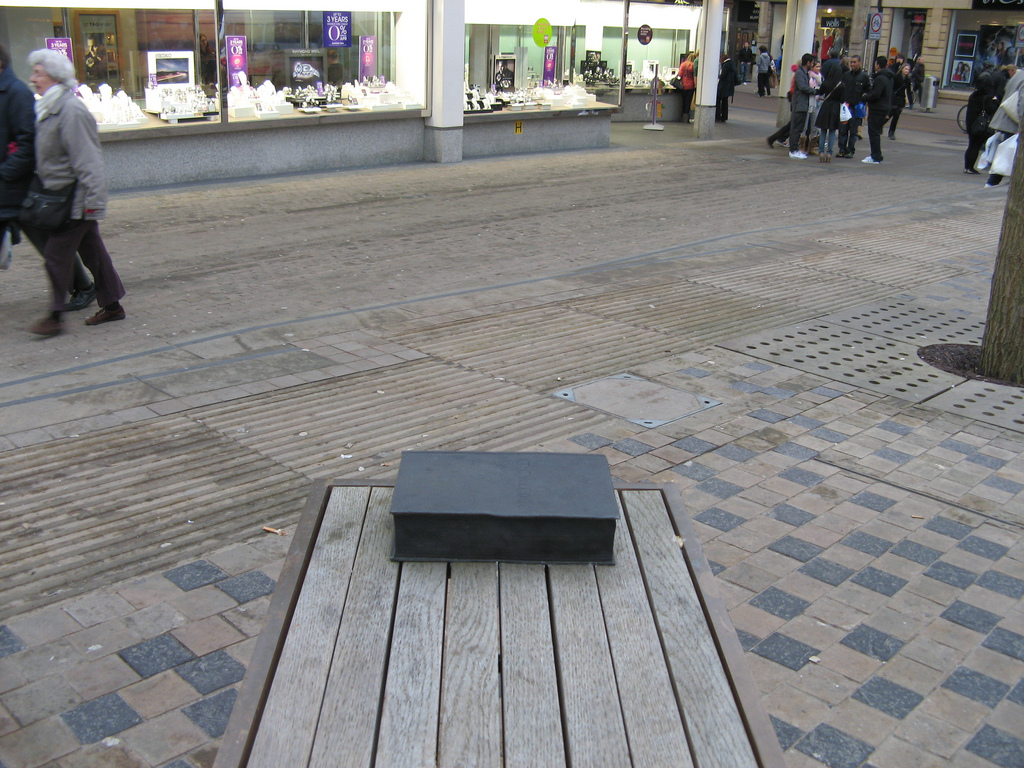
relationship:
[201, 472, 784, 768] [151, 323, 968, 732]
table in ground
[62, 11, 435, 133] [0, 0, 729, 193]
window in a store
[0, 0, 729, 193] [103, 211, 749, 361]
store near a pathway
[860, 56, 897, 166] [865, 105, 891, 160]
person in jeans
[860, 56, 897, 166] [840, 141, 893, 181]
person in shoe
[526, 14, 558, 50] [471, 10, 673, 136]
sign on a window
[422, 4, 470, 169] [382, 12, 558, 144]
pillar on a wall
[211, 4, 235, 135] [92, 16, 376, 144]
divider in a window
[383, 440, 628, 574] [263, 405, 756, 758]
box on a table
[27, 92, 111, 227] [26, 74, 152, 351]
gray coat on a body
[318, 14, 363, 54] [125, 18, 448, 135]
poster on a window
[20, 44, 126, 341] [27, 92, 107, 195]
woman in gray coat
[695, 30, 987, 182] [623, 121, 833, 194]
people walking on sidewalk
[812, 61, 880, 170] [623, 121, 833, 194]
person walking on sidewalk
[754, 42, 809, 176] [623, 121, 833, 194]
person walking on sidewalk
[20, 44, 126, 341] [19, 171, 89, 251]
woman walking with black purse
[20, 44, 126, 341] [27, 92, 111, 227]
woman wearing gray coat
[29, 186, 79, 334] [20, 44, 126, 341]
leg on woman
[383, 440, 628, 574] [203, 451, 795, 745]
box on table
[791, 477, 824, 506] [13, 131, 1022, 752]
brick on sidewalk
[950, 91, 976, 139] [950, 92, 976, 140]
bike has wheel